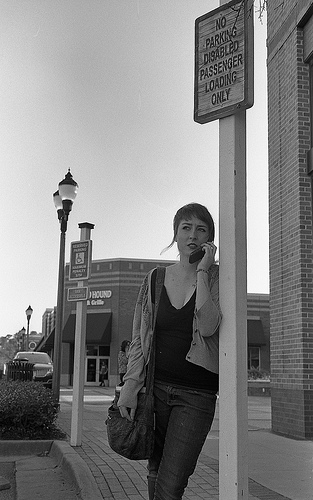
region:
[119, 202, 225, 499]
Woman talking on the phone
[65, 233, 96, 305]
Wooden handicap parking sign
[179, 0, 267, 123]
Wooden no parking sign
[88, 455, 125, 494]
Brick border along the sidewalk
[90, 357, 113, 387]
person standing against the building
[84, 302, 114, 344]
awning over a restaurant entrance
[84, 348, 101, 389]
doors to restaurant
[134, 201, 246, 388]
woman in a black shirt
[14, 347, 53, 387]
car parked on the side of the road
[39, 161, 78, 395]
double lamp street light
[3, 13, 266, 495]
Black and white photo.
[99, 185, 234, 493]
Woman leaning against a lamp post.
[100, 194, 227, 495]
Woman talking on a cell phone.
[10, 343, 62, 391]
Car parked on the side of the road.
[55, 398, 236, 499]
Brick sidewalk.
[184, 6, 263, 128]
No parking sign.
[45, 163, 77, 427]
Street light post.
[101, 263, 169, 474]
Large handbag on the woman's shoulder.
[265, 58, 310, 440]
Brick wall behind the woman.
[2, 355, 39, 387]
Trash can beside the sidewalk.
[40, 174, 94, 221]
Street lamps on side walk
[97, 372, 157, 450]
Bag near woman's thigh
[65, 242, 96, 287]
Handicap only parking sign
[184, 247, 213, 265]
Cell phone near woman's face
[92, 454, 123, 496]
Brick side walk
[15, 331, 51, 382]
Buick parked near sidewalk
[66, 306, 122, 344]
Awning on brick building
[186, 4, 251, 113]
No parking sign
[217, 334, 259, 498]
Wooden post on sidewalk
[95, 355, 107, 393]
Man leaning agaisnt doorway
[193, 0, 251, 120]
"no parking, disabled loading only" sign on post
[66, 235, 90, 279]
handicapped parking only sign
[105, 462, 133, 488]
some bricks from the sidewalk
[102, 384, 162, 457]
a woman's hand hanging over her purse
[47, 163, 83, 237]
two street lamps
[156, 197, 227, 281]
woman holding phone next to face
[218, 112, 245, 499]
a sign post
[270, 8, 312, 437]
a brick wall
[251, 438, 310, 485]
a cross section of side walk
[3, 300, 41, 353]
a row of street lights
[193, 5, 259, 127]
a sign on top of the pole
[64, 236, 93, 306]
a sign of handicapped parking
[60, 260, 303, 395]
a building behind the woman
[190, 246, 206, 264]
the cellphone in the woman's hands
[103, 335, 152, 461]
the woman's purse hanging from her shoulder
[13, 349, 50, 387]
a car parked in the parking lot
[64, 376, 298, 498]
the sidewalk next to the buildings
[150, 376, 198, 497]
the woman's blue jeans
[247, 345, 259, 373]
the windows of the building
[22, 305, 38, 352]
a light post behind the car